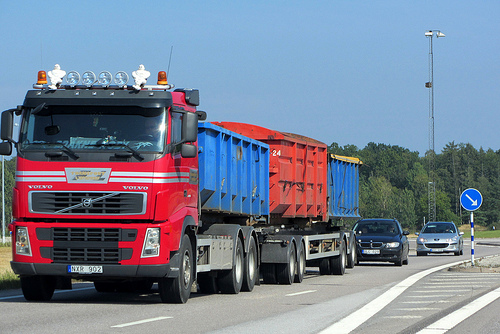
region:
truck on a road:
[4, 53, 371, 317]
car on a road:
[412, 213, 468, 260]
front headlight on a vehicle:
[136, 221, 166, 265]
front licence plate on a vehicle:
[61, 258, 113, 278]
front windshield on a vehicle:
[14, 93, 173, 168]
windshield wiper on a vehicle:
[79, 136, 151, 167]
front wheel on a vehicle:
[155, 224, 202, 308]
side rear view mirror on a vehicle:
[166, 100, 203, 165]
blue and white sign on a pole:
[454, 181, 487, 216]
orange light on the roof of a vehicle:
[151, 68, 171, 96]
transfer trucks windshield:
[27, 96, 182, 156]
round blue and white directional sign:
[450, 178, 490, 218]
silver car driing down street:
[412, 214, 466, 261]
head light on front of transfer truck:
[137, 223, 177, 264]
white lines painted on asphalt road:
[362, 257, 498, 330]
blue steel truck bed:
[197, 116, 279, 235]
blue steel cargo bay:
[328, 150, 383, 232]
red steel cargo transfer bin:
[231, 112, 341, 230]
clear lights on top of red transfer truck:
[62, 66, 150, 94]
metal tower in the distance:
[408, 18, 469, 250]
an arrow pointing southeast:
[460, 191, 479, 211]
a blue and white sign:
[457, 189, 487, 276]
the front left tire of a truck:
[177, 237, 197, 297]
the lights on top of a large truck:
[36, 61, 173, 93]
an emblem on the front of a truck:
[62, 165, 114, 185]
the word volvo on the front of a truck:
[27, 183, 54, 190]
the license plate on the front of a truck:
[65, 260, 104, 275]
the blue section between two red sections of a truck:
[191, 121, 271, 213]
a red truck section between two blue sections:
[265, 130, 325, 225]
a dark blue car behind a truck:
[359, 216, 404, 259]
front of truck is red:
[15, 69, 184, 270]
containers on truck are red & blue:
[193, 103, 398, 236]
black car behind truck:
[345, 189, 413, 271]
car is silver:
[421, 209, 473, 266]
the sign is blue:
[450, 173, 495, 217]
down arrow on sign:
[453, 182, 485, 217]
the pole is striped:
[465, 211, 487, 271]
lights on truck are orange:
[27, 47, 179, 90]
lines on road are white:
[109, 221, 489, 325]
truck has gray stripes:
[12, 159, 209, 191]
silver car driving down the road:
[416, 213, 464, 254]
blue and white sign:
[457, 183, 486, 265]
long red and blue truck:
[4, 64, 377, 307]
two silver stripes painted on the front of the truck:
[18, 166, 188, 187]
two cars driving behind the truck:
[343, 182, 473, 274]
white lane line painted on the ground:
[111, 307, 175, 330]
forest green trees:
[353, 146, 499, 238]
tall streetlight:
[416, 26, 453, 231]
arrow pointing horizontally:
[460, 184, 483, 212]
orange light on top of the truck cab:
[156, 67, 169, 89]